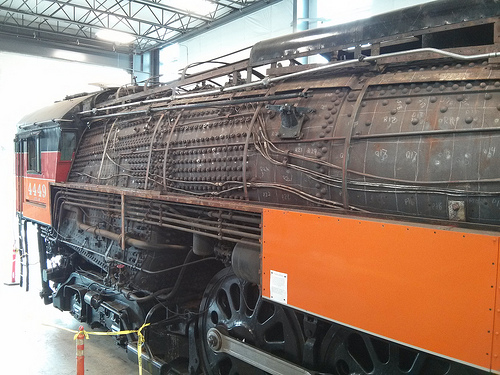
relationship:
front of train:
[14, 82, 157, 228] [2, 0, 497, 373]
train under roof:
[2, 0, 497, 373] [1, 3, 282, 68]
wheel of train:
[197, 274, 312, 371] [2, 0, 497, 373]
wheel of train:
[322, 315, 486, 375] [2, 0, 497, 373]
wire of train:
[105, 150, 371, 214] [2, 0, 497, 373]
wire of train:
[101, 117, 374, 214] [2, 0, 497, 373]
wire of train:
[64, 170, 368, 216] [2, 0, 497, 373]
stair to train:
[15, 211, 32, 300] [2, 0, 497, 373]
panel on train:
[256, 207, 499, 372] [2, 0, 497, 373]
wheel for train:
[197, 274, 312, 371] [2, 0, 497, 373]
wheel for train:
[322, 315, 486, 375] [2, 0, 497, 373]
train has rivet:
[2, 0, 497, 373] [180, 110, 189, 123]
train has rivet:
[2, 0, 497, 373] [189, 121, 201, 132]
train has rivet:
[2, 0, 497, 373] [201, 138, 209, 144]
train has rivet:
[2, 0, 497, 373] [217, 158, 225, 165]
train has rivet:
[2, 0, 497, 373] [229, 173, 242, 182]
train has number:
[2, 0, 497, 373] [20, 181, 55, 201]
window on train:
[27, 139, 36, 174] [2, 0, 497, 373]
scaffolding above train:
[0, 3, 317, 66] [2, 0, 497, 373]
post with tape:
[73, 324, 88, 374] [13, 248, 152, 375]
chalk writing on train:
[376, 95, 460, 164] [2, 0, 497, 373]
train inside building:
[2, 0, 497, 373] [1, 0, 441, 374]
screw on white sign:
[268, 271, 275, 275] [266, 270, 287, 305]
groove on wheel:
[224, 277, 242, 315] [196, 263, 312, 369]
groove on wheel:
[238, 280, 261, 320] [196, 263, 312, 369]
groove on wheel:
[260, 318, 291, 345] [196, 263, 312, 369]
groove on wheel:
[254, 295, 281, 323] [196, 263, 312, 369]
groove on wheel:
[206, 307, 223, 325] [196, 263, 312, 369]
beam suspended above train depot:
[52, 0, 182, 38] [13, 4, 496, 364]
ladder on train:
[18, 216, 28, 291] [2, 0, 497, 373]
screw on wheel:
[204, 333, 218, 349] [197, 274, 312, 371]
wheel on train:
[197, 274, 312, 371] [9, 71, 499, 367]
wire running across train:
[105, 150, 371, 214] [2, 0, 497, 373]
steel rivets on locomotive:
[75, 115, 264, 185] [14, 0, 498, 372]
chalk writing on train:
[363, 95, 458, 177] [2, 0, 497, 373]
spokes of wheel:
[216, 287, 274, 335] [197, 274, 312, 371]